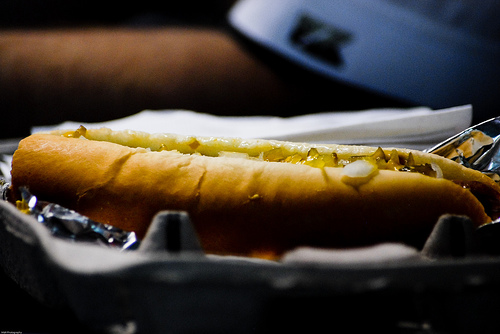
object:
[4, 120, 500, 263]
bun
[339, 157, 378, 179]
onions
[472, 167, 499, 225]
tip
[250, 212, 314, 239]
shadwo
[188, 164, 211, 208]
wrinkles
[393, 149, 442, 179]
relish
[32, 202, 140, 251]
foil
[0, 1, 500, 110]
man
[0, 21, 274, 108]
arm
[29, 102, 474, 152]
napkin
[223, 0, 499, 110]
shirt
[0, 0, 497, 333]
picture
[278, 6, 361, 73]
logo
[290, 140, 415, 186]
garnish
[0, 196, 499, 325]
tin